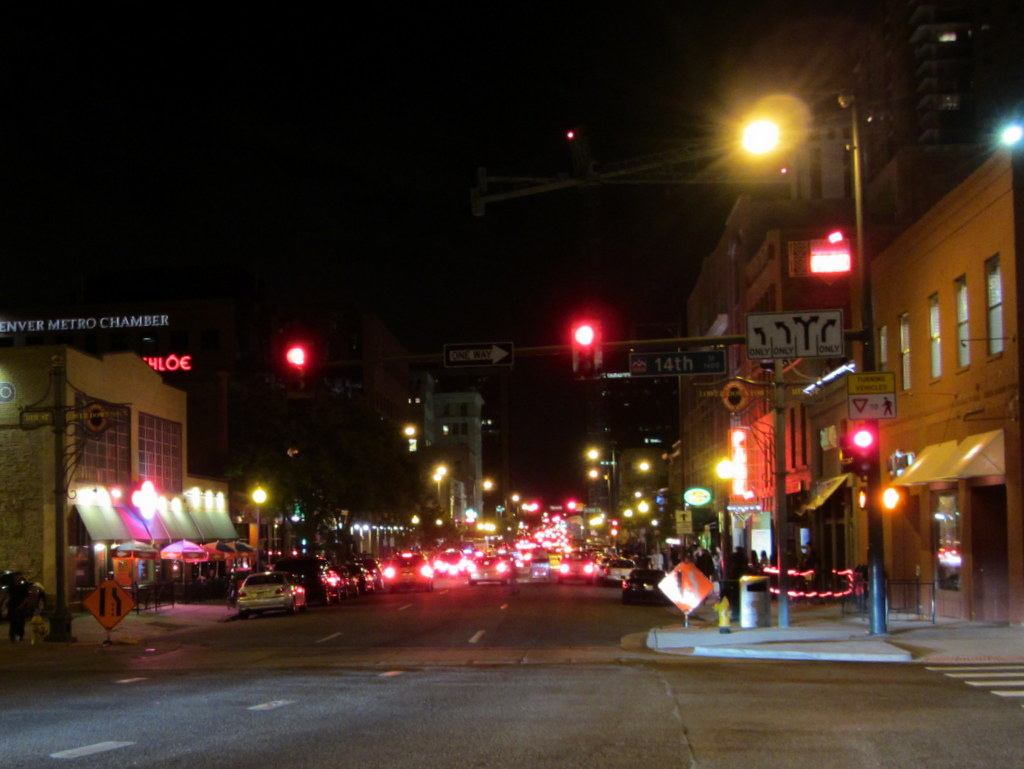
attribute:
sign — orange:
[647, 535, 717, 640]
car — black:
[613, 553, 681, 621]